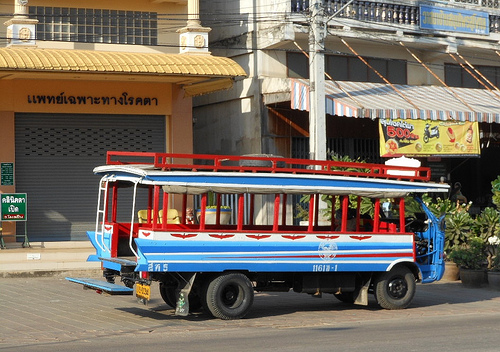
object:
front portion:
[334, 160, 449, 310]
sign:
[0, 193, 26, 221]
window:
[26, 4, 157, 46]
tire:
[202, 270, 255, 320]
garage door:
[13, 112, 169, 244]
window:
[155, 192, 229, 232]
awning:
[1, 47, 248, 97]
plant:
[433, 207, 499, 271]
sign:
[0, 162, 14, 186]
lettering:
[27, 91, 159, 106]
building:
[0, 0, 247, 245]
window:
[156, 187, 203, 229]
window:
[277, 192, 312, 232]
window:
[286, 51, 409, 86]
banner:
[378, 119, 481, 158]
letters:
[135, 238, 349, 272]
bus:
[65, 150, 450, 320]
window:
[204, 191, 239, 231]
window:
[241, 193, 276, 231]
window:
[312, 193, 343, 232]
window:
[347, 195, 376, 233]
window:
[167, 190, 202, 230]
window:
[167, 191, 312, 231]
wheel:
[373, 263, 417, 309]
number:
[135, 282, 150, 301]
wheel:
[199, 274, 255, 321]